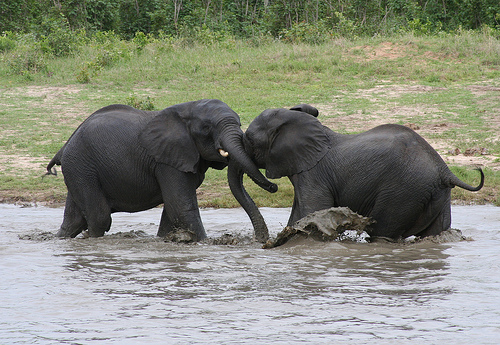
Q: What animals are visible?
A: Elephants.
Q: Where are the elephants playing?
A: Lake.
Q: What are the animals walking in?
A: Water.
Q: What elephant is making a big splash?
A: Right.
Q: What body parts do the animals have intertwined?
A: Trunks.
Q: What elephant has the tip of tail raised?
A: Right.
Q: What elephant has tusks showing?
A: Left.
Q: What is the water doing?
A: Splashing on the elephant.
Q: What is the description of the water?
A: It's brown.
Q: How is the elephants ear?
A: Facing backwards.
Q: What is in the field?
A: Weeds in the grass.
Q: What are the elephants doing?
A: Standing in the water.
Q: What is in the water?
A: Two elephants.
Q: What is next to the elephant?
A: Water.